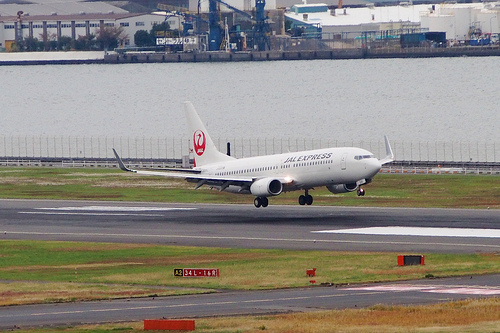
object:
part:
[241, 184, 284, 214]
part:
[21, 150, 66, 171]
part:
[393, 148, 434, 158]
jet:
[107, 98, 398, 209]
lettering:
[282, 151, 335, 164]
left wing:
[378, 133, 397, 166]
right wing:
[105, 145, 295, 186]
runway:
[4, 185, 498, 256]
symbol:
[191, 129, 207, 156]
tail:
[178, 97, 236, 168]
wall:
[1, 156, 498, 172]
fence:
[1, 130, 500, 176]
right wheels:
[261, 196, 269, 208]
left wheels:
[297, 194, 306, 205]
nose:
[357, 158, 386, 175]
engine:
[248, 175, 285, 198]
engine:
[326, 179, 360, 196]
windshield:
[361, 154, 371, 159]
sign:
[183, 267, 221, 278]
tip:
[109, 147, 132, 171]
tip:
[382, 133, 396, 158]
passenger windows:
[331, 159, 334, 163]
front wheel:
[361, 189, 365, 196]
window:
[328, 160, 330, 164]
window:
[292, 163, 295, 167]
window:
[288, 164, 291, 168]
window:
[267, 166, 270, 171]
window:
[257, 168, 260, 172]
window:
[249, 169, 251, 173]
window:
[312, 161, 314, 165]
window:
[304, 162, 307, 167]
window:
[236, 170, 239, 174]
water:
[1, 59, 498, 153]